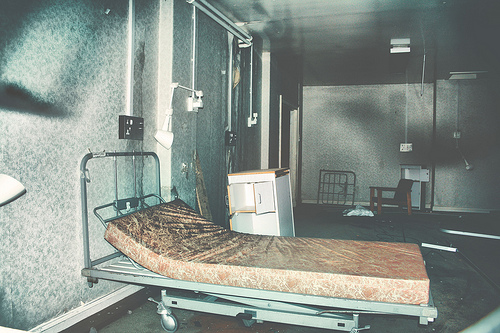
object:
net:
[334, 130, 364, 140]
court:
[385, 118, 479, 152]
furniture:
[280, 159, 427, 226]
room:
[64, 16, 455, 282]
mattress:
[103, 198, 430, 306]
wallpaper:
[37, 37, 101, 82]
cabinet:
[227, 167, 297, 236]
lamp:
[430, 118, 458, 184]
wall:
[318, 93, 356, 121]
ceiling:
[322, 12, 361, 29]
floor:
[314, 217, 334, 227]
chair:
[369, 179, 413, 216]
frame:
[67, 138, 150, 190]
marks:
[150, 223, 195, 253]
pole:
[420, 54, 426, 95]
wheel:
[159, 311, 178, 332]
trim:
[148, 21, 182, 60]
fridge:
[277, 181, 291, 194]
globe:
[174, 91, 196, 112]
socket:
[118, 115, 144, 141]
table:
[317, 169, 356, 208]